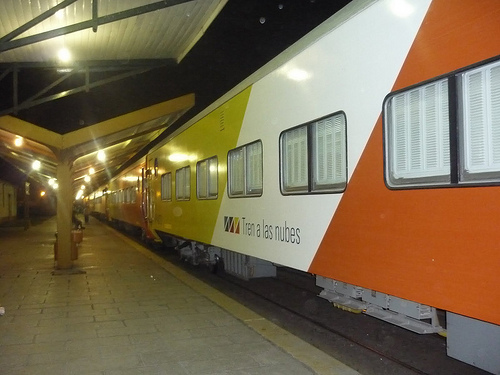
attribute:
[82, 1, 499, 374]
train — yellow, shown at night, parked, large, in the dark, orange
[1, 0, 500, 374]
train station — shown at night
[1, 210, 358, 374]
sidewalk — yellow, tiled, made of concrete, made of brick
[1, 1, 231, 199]
awning — large, white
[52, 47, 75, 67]
light — round, turned on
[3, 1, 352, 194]
sky — pitch black, dark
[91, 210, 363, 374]
line — yellow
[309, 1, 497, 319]
section — orange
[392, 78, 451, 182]
shutters — white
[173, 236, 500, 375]
undercarriage — gray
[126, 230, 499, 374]
concrete — gray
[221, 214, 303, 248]
logo — colorful